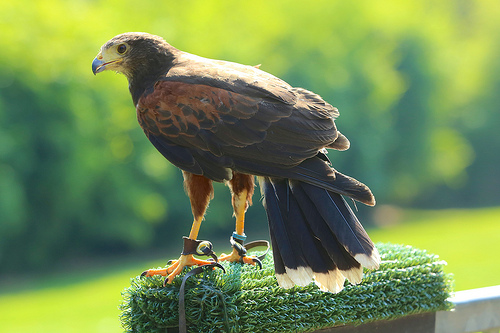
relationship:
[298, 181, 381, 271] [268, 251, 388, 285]
feather with tips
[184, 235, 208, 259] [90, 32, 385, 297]
strap on bird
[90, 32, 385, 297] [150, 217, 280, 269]
bird with feet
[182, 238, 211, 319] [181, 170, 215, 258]
tether tied to leg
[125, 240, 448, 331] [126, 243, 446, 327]
mat on perch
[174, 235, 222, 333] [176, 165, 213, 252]
tether on leg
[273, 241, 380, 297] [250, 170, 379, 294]
tips on feathers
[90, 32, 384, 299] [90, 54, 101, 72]
bird has beak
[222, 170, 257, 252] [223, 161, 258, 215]
leg has feathers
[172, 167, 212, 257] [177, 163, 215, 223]
leg has feathers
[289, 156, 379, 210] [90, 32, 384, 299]
feather on bird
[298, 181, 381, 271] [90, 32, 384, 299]
feather on bird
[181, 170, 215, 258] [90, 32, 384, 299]
leg on bird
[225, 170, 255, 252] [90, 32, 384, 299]
leg on bird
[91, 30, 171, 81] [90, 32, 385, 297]
head on bird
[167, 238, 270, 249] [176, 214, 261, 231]
cups around leg